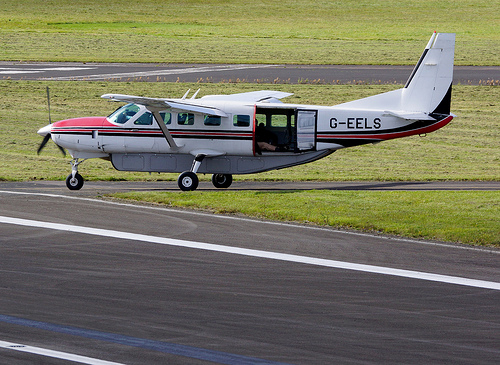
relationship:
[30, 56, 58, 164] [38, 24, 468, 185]
propeller on plane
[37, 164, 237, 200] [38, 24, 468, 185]
wheels on plane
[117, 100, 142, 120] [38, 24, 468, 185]
cockpit window on plane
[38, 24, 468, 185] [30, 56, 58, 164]
plane has propeller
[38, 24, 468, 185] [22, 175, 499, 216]
plane on ground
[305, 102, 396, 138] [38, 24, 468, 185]
letters on plane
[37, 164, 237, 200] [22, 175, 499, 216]
wheels on ground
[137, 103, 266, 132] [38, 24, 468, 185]
windows on plane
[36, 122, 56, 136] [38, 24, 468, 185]
rotor on plane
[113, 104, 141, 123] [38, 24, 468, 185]
cockpit window on plane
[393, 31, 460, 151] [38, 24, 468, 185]
tail on plane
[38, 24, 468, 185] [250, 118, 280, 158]
plane carries passengers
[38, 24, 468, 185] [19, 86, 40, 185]
plane near field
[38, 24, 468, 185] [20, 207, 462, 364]
plane on tarmac